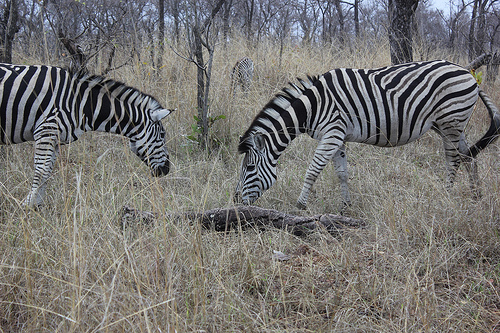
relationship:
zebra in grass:
[217, 51, 499, 208] [0, 28, 497, 331]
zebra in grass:
[0, 63, 175, 212] [0, 28, 497, 331]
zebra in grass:
[231, 60, 499, 215] [68, 263, 320, 321]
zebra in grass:
[216, 35, 267, 106] [68, 263, 320, 321]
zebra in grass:
[0, 63, 175, 212] [68, 263, 320, 321]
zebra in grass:
[0, 63, 175, 212] [57, 171, 199, 280]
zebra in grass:
[231, 60, 499, 215] [57, 171, 199, 280]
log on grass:
[109, 207, 364, 252] [25, 182, 464, 330]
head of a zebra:
[129, 93, 175, 177] [0, 63, 175, 212]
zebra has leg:
[236, 54, 498, 224] [320, 137, 361, 221]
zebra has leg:
[236, 54, 498, 224] [438, 117, 465, 192]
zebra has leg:
[231, 60, 499, 215] [19, 140, 59, 210]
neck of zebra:
[270, 84, 305, 147] [236, 54, 498, 224]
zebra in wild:
[236, 54, 498, 224] [88, 7, 330, 76]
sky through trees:
[139, 3, 373, 21] [155, 0, 390, 56]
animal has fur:
[0, 53, 180, 208] [61, 77, 97, 102]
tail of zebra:
[222, 56, 252, 94] [229, 54, 492, 238]